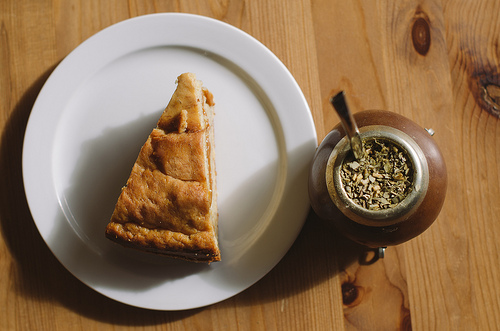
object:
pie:
[106, 71, 224, 265]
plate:
[22, 12, 320, 312]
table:
[0, 0, 500, 328]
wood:
[314, 0, 498, 109]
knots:
[467, 62, 497, 117]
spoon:
[330, 87, 378, 168]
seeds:
[361, 190, 396, 201]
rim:
[123, 19, 143, 34]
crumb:
[171, 111, 189, 133]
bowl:
[306, 109, 448, 256]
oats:
[370, 163, 403, 189]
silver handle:
[423, 128, 437, 136]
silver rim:
[411, 159, 430, 187]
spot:
[405, 18, 434, 54]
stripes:
[253, 0, 317, 143]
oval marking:
[336, 281, 361, 304]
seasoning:
[368, 173, 386, 193]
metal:
[376, 208, 393, 217]